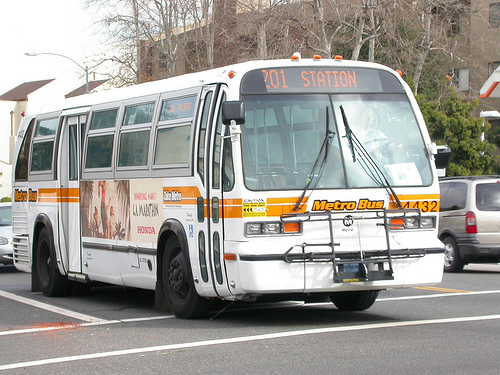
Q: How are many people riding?
A: On bus.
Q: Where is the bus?
A: On the street.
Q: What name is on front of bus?
A: Metro bus.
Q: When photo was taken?
A: Daytime.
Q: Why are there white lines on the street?
A: Dividers.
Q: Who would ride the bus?
A: People.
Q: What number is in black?
A: 4432.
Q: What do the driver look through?
A: Window.